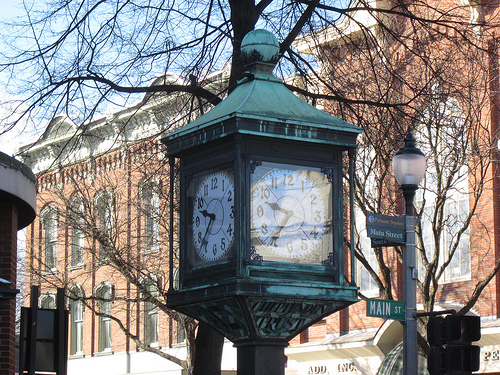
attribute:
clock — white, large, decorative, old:
[159, 27, 364, 374]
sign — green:
[365, 297, 407, 321]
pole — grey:
[400, 191, 419, 374]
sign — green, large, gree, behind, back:
[366, 299, 405, 320]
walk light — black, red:
[425, 311, 482, 374]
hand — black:
[201, 209, 217, 221]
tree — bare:
[17, 0, 488, 113]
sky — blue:
[1, 2, 234, 140]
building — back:
[20, 4, 496, 364]